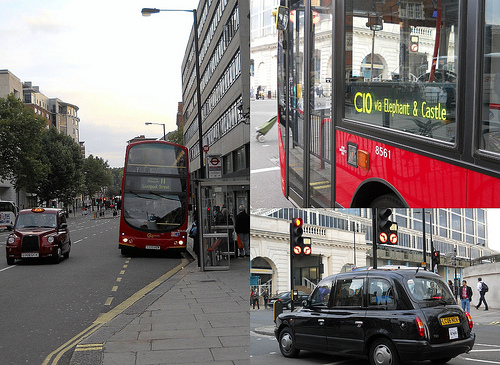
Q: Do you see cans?
A: No, there are no cans.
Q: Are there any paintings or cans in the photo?
A: No, there are no cans or paintings.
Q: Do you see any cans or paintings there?
A: No, there are no cans or paintings.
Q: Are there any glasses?
A: No, there are no glasses.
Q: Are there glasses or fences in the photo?
A: No, there are no glasses or fences.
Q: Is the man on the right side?
A: Yes, the man is on the right of the image.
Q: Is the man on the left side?
A: No, the man is on the right of the image.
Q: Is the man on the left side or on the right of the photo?
A: The man is on the right of the image.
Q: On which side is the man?
A: The man is on the right of the image.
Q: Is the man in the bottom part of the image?
A: Yes, the man is in the bottom of the image.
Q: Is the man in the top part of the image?
A: No, the man is in the bottom of the image.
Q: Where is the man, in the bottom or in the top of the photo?
A: The man is in the bottom of the image.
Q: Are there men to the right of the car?
A: Yes, there is a man to the right of the car.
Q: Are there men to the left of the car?
A: No, the man is to the right of the car.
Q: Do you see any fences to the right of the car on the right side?
A: No, there is a man to the right of the car.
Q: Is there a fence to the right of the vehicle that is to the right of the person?
A: No, there is a man to the right of the car.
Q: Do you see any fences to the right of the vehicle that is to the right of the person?
A: No, there is a man to the right of the car.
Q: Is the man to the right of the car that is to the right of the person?
A: Yes, the man is to the right of the car.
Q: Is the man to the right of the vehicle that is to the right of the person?
A: Yes, the man is to the right of the car.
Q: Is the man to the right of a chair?
A: No, the man is to the right of the car.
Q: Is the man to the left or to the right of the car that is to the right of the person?
A: The man is to the right of the car.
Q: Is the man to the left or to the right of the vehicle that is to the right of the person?
A: The man is to the right of the car.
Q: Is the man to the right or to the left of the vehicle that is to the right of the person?
A: The man is to the right of the car.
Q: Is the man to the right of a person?
A: Yes, the man is to the right of a person.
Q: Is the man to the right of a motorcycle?
A: No, the man is to the right of a person.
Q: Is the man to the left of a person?
A: No, the man is to the right of a person.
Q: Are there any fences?
A: No, there are no fences.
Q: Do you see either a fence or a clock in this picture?
A: No, there are no fences or clocks.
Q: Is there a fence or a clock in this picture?
A: No, there are no fences or clocks.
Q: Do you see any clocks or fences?
A: No, there are no fences or clocks.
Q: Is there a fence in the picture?
A: No, there are no fences.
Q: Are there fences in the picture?
A: No, there are no fences.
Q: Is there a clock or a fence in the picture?
A: No, there are no fences or clocks.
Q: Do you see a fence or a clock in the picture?
A: No, there are no fences or clocks.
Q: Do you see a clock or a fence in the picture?
A: No, there are no fences or clocks.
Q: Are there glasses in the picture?
A: No, there are no glasses.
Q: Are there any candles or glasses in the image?
A: No, there are no glasses or candles.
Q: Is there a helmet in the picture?
A: No, there are no helmets.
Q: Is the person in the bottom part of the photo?
A: Yes, the person is in the bottom of the image.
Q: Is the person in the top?
A: No, the person is in the bottom of the image.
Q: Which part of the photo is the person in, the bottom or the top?
A: The person is in the bottom of the image.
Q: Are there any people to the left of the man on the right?
A: Yes, there is a person to the left of the man.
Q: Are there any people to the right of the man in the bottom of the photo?
A: No, the person is to the left of the man.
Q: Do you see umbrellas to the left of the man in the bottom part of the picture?
A: No, there is a person to the left of the man.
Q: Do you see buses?
A: Yes, there is a bus.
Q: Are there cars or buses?
A: Yes, there is a bus.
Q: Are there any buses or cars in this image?
A: Yes, there is a bus.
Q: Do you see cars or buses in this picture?
A: Yes, there is a bus.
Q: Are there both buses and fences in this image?
A: No, there is a bus but no fences.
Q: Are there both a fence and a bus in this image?
A: No, there is a bus but no fences.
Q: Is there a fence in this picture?
A: No, there are no fences.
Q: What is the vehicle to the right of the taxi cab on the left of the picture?
A: The vehicle is a bus.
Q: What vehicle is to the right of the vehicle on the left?
A: The vehicle is a bus.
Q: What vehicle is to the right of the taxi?
A: The vehicle is a bus.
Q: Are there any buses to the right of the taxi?
A: Yes, there is a bus to the right of the taxi.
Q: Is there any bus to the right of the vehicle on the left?
A: Yes, there is a bus to the right of the taxi.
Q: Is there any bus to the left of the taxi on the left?
A: No, the bus is to the right of the taxi.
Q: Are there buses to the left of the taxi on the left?
A: No, the bus is to the right of the taxi.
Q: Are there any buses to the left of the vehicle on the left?
A: No, the bus is to the right of the taxi.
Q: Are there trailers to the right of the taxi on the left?
A: No, there is a bus to the right of the cab.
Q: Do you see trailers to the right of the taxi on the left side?
A: No, there is a bus to the right of the cab.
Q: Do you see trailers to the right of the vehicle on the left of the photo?
A: No, there is a bus to the right of the cab.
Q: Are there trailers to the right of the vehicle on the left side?
A: No, there is a bus to the right of the cab.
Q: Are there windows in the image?
A: Yes, there is a window.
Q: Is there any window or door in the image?
A: Yes, there is a window.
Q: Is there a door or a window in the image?
A: Yes, there is a window.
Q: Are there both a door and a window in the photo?
A: Yes, there are both a window and a door.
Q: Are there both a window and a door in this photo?
A: Yes, there are both a window and a door.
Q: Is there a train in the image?
A: No, there are no trains.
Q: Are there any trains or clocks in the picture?
A: No, there are no trains or clocks.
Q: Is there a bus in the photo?
A: Yes, there is a bus.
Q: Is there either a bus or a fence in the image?
A: Yes, there is a bus.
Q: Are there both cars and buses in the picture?
A: Yes, there are both a bus and a car.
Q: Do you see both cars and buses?
A: Yes, there are both a bus and a car.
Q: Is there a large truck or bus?
A: Yes, there is a large bus.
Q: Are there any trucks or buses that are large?
A: Yes, the bus is large.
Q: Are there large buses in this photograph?
A: Yes, there is a large bus.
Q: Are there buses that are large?
A: Yes, there is a bus that is large.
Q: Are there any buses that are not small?
A: Yes, there is a large bus.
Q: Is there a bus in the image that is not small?
A: Yes, there is a large bus.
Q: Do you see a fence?
A: No, there are no fences.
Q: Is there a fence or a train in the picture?
A: No, there are no fences or trains.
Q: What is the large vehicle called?
A: The vehicle is a bus.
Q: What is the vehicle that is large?
A: The vehicle is a bus.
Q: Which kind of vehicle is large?
A: The vehicle is a bus.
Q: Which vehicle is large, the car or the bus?
A: The bus is large.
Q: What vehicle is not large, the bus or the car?
A: The car is not large.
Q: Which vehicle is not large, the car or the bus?
A: The car is not large.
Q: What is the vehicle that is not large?
A: The vehicle is a car.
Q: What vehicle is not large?
A: The vehicle is a car.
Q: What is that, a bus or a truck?
A: That is a bus.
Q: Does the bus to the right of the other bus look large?
A: Yes, the bus is large.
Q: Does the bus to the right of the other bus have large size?
A: Yes, the bus is large.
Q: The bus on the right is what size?
A: The bus is large.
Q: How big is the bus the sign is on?
A: The bus is large.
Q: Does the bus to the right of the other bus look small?
A: No, the bus is large.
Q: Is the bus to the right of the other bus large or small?
A: The bus is large.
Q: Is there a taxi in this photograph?
A: Yes, there is a taxi.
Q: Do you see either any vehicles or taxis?
A: Yes, there is a taxi.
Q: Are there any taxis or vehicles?
A: Yes, there is a taxi.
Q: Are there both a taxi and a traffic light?
A: Yes, there are both a taxi and a traffic light.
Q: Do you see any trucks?
A: No, there are no trucks.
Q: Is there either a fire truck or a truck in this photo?
A: No, there are no trucks or fire trucks.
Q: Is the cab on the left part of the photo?
A: Yes, the cab is on the left of the image.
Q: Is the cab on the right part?
A: No, the cab is on the left of the image.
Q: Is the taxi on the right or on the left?
A: The taxi is on the left of the image.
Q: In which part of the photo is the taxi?
A: The taxi is on the left of the image.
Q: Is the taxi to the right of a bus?
A: No, the taxi is to the left of a bus.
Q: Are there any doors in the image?
A: Yes, there is a door.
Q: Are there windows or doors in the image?
A: Yes, there is a door.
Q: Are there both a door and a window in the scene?
A: Yes, there are both a door and a window.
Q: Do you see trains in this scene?
A: No, there are no trains.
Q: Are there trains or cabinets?
A: No, there are no trains or cabinets.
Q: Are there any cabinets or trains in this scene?
A: No, there are no trains or cabinets.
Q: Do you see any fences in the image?
A: No, there are no fences.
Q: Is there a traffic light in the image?
A: Yes, there is a traffic light.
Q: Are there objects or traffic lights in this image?
A: Yes, there is a traffic light.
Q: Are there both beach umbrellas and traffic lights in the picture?
A: No, there is a traffic light but no beach umbrellas.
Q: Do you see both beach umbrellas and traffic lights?
A: No, there is a traffic light but no beach umbrellas.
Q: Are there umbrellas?
A: No, there are no umbrellas.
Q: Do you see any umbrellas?
A: No, there are no umbrellas.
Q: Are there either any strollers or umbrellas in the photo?
A: No, there are no umbrellas or strollers.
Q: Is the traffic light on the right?
A: Yes, the traffic light is on the right of the image.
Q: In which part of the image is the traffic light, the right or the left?
A: The traffic light is on the right of the image.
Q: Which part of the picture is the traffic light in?
A: The traffic light is on the right of the image.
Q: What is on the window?
A: The sign is on the window.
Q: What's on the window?
A: The sign is on the window.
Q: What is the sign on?
A: The sign is on the window.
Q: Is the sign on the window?
A: Yes, the sign is on the window.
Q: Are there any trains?
A: No, there are no trains.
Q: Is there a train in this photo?
A: No, there are no trains.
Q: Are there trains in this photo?
A: No, there are no trains.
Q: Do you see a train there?
A: No, there are no trains.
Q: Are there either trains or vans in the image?
A: No, there are no trains or vans.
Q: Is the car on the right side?
A: Yes, the car is on the right of the image.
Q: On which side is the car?
A: The car is on the right of the image.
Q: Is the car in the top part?
A: No, the car is in the bottom of the image.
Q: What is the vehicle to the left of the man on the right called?
A: The vehicle is a car.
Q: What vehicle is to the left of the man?
A: The vehicle is a car.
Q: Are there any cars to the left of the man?
A: Yes, there is a car to the left of the man.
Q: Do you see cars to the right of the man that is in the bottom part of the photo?
A: No, the car is to the left of the man.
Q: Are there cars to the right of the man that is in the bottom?
A: No, the car is to the left of the man.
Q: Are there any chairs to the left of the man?
A: No, there is a car to the left of the man.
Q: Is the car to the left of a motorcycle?
A: No, the car is to the left of the man.